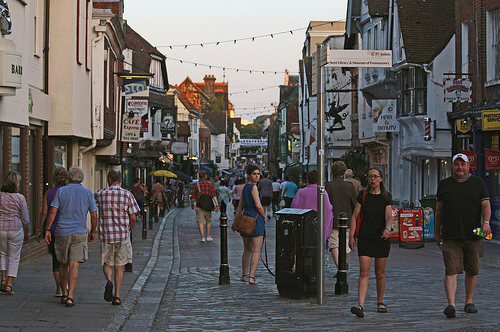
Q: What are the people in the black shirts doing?
A: Walking.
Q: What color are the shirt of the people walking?
A: Black.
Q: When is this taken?
A: During the day.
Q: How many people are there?
A: Dozens.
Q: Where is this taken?
A: Outside in a city.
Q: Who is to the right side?
A: A man and woman.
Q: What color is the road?
A: Gray.